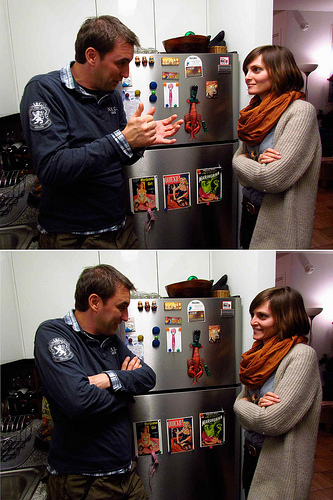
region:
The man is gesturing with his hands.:
[19, 16, 174, 237]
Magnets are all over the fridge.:
[119, 46, 233, 241]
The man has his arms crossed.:
[38, 264, 154, 492]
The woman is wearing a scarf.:
[231, 330, 313, 378]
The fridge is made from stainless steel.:
[122, 295, 237, 493]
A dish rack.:
[0, 391, 39, 460]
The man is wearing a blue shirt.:
[9, 70, 137, 224]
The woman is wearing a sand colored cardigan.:
[237, 336, 326, 493]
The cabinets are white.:
[7, 1, 217, 53]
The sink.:
[1, 464, 38, 497]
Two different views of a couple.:
[18, 9, 323, 485]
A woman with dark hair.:
[235, 42, 313, 192]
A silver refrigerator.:
[133, 52, 247, 249]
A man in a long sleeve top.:
[17, 14, 176, 214]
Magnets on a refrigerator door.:
[131, 55, 235, 100]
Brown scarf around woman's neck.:
[236, 286, 315, 389]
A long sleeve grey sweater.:
[235, 49, 321, 248]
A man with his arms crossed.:
[26, 267, 162, 490]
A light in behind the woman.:
[292, 48, 322, 101]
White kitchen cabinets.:
[3, 254, 252, 347]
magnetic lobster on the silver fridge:
[177, 330, 215, 382]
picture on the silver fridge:
[166, 408, 203, 454]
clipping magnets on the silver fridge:
[151, 322, 166, 358]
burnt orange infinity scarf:
[242, 335, 309, 383]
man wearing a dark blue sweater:
[34, 307, 158, 468]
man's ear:
[86, 294, 104, 313]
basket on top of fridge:
[159, 274, 226, 298]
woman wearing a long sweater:
[237, 330, 331, 497]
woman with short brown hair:
[246, 282, 328, 353]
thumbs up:
[106, 105, 157, 152]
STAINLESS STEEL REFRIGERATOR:
[119, 291, 265, 495]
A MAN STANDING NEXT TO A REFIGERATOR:
[38, 263, 147, 496]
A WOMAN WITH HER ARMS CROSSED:
[228, 283, 332, 489]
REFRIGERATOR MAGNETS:
[132, 298, 235, 379]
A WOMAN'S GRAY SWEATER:
[234, 337, 320, 493]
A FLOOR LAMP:
[301, 301, 326, 344]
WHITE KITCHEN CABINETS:
[85, 251, 228, 296]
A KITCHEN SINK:
[4, 459, 53, 498]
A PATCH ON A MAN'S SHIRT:
[40, 329, 79, 370]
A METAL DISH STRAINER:
[3, 415, 36, 465]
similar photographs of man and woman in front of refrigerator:
[26, 32, 307, 453]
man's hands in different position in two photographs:
[21, 18, 182, 440]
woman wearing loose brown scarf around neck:
[232, 270, 314, 407]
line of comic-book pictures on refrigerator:
[125, 405, 231, 459]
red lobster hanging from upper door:
[182, 317, 210, 393]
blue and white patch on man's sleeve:
[39, 324, 72, 378]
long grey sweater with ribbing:
[211, 343, 319, 483]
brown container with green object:
[154, 266, 215, 299]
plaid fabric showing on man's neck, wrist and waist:
[19, 301, 157, 487]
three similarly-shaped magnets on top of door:
[135, 291, 155, 314]